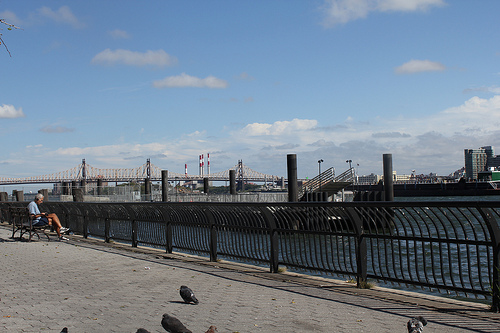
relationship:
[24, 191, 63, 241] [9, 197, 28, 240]
man sitting on bench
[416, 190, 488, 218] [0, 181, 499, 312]
water behind barge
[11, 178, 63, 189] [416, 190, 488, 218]
bridge crosses water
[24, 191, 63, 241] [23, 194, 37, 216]
man wearing shirt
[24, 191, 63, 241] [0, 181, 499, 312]
man by barge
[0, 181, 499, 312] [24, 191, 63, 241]
barge by man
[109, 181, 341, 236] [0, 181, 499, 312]
barge by barge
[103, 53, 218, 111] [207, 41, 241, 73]
clouds are in sky